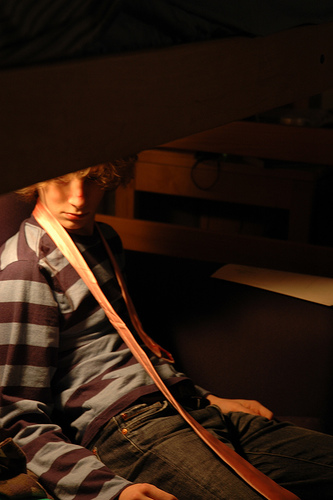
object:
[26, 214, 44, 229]
stripe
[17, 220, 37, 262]
stripe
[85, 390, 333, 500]
jeans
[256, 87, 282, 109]
ground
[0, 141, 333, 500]
brown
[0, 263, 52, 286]
black stripe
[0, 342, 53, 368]
black stripe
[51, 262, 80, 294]
black stripe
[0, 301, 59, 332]
black stripe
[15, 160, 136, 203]
hair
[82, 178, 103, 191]
eye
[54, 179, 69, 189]
eye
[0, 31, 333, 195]
plank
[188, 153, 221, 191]
black circle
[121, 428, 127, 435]
clasp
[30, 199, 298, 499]
tie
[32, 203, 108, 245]
neck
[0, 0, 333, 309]
bed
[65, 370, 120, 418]
stripes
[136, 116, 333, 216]
mattress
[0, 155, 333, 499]
boy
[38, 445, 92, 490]
stripe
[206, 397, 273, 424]
hand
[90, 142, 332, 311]
shelf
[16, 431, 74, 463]
stripe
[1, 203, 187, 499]
shirt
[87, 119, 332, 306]
desk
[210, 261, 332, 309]
paper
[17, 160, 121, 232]
head